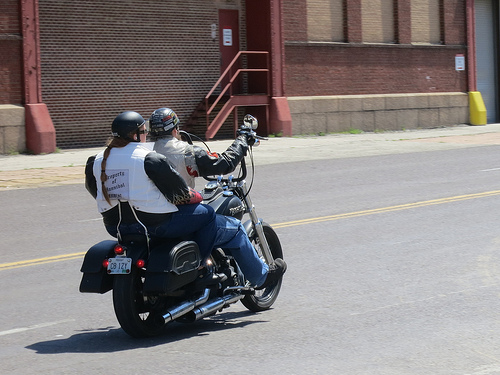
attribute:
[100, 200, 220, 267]
jeans — blue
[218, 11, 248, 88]
door — red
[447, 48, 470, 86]
sign — rectangular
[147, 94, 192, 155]
helmet — colorful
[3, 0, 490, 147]
building — brick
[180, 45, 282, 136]
staircase — metal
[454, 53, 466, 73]
sign — red, white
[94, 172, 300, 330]
motorcycle — black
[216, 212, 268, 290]
jeans — light-colored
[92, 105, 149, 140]
helmet — black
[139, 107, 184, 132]
helmet — black, yellow, red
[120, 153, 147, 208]
vest — white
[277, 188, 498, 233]
line — yellow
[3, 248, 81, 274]
line — yellow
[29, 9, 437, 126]
wall — brick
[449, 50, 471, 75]
sign — rectangular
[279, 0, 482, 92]
building — brick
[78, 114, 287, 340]
motorcycle — black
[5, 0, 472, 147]
brick building — red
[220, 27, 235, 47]
sign — white, square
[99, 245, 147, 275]
lights — three, red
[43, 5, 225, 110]
wall — red, brick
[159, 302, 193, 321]
muffler — silver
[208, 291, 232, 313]
muffler — silver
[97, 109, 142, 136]
helmet — black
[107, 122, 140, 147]
helmet — black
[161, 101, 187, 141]
helmet — black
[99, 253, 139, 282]
plate — license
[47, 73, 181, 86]
grout — white